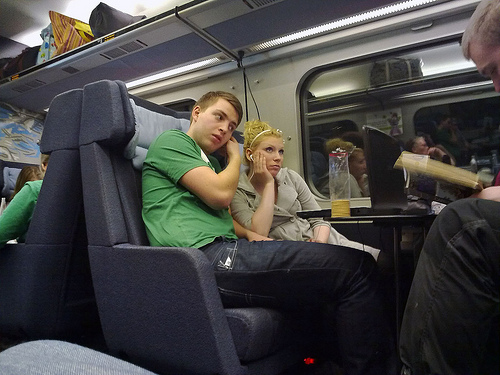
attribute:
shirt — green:
[137, 127, 239, 249]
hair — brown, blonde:
[240, 117, 288, 150]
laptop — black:
[292, 122, 408, 218]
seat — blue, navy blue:
[81, 76, 301, 373]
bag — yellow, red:
[46, 11, 94, 55]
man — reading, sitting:
[389, 1, 499, 374]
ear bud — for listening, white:
[249, 154, 253, 162]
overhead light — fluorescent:
[115, 0, 435, 90]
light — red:
[300, 355, 315, 366]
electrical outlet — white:
[215, 48, 249, 65]